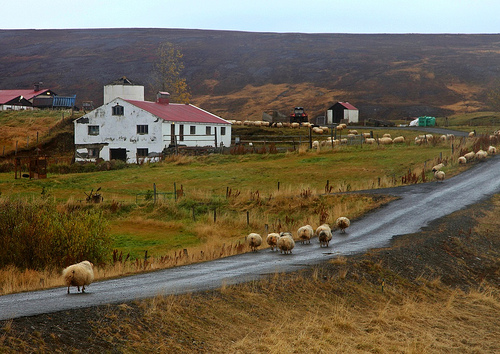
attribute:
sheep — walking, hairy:
[63, 260, 94, 294]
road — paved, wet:
[0, 123, 500, 322]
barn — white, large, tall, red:
[75, 91, 233, 163]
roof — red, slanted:
[113, 97, 232, 124]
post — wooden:
[246, 210, 250, 227]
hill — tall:
[0, 28, 499, 133]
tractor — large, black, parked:
[290, 106, 310, 124]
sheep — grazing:
[432, 162, 445, 173]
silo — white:
[104, 83, 145, 103]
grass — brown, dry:
[0, 29, 499, 352]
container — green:
[417, 116, 436, 127]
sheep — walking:
[62, 120, 500, 293]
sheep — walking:
[247, 231, 262, 250]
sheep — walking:
[337, 215, 351, 233]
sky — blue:
[0, 0, 499, 33]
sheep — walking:
[297, 224, 314, 244]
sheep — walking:
[267, 232, 280, 252]